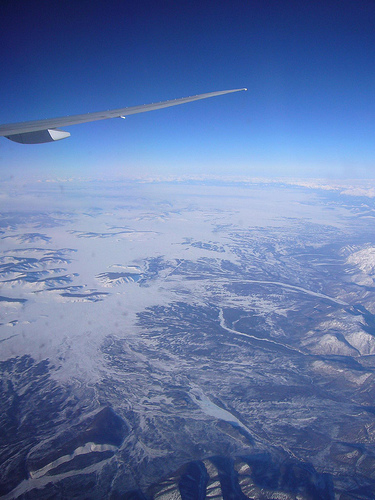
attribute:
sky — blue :
[4, 0, 364, 78]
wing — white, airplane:
[5, 81, 251, 147]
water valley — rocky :
[185, 388, 257, 439]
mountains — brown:
[292, 181, 373, 357]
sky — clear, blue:
[4, 5, 373, 187]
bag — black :
[34, 437, 95, 473]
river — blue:
[205, 305, 311, 357]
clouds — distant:
[267, 175, 346, 196]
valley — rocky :
[34, 366, 250, 492]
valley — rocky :
[4, 268, 91, 366]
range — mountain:
[1, 171, 374, 498]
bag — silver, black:
[12, 126, 80, 156]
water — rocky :
[283, 377, 346, 479]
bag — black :
[163, 465, 267, 498]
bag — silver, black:
[302, 290, 345, 313]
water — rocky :
[211, 294, 272, 361]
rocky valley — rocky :
[82, 311, 191, 423]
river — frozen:
[213, 302, 231, 339]